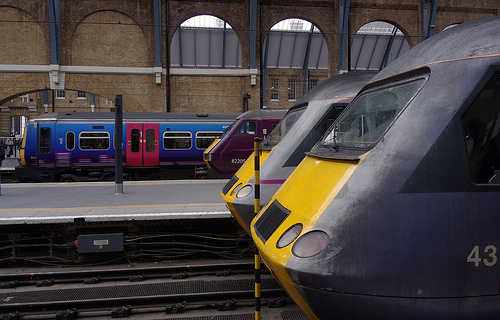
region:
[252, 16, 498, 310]
a grey and yellow train parked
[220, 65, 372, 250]
a grey and yellow train parked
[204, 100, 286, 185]
a grey and yellow train parked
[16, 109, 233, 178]
a blue red and yellow train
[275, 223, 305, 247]
a round train headlight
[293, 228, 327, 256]
a round train headlight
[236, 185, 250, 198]
a round train headlight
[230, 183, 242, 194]
a round train headlight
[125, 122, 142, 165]
red door of a train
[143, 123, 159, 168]
red door of a train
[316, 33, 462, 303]
yellow and gray train in station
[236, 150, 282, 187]
yellow and gray train in station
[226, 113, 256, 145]
purple and gray train in station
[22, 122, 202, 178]
red and blue train in station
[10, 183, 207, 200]
gray platform in train station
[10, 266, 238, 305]
gray and brown metal tracks in station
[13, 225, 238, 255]
gray and brown metal tracks in station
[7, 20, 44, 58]
brown and tan wall in train station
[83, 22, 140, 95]
brown gray and tan wall in train station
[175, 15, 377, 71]
windows in train station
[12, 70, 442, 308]
several trains in photograph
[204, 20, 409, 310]
two black and yellow trains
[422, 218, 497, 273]
white numbers on black train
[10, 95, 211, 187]
blue and red train in photograph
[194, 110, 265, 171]
purple and yellow train in photograph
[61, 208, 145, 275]
black box with wires on train tracks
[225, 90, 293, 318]
black and yellow striped pole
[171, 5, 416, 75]
three arched windows in photo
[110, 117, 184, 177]
red doors on blue train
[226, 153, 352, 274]
yellow noses of trains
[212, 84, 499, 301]
trains parked in station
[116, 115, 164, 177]
pink doors on train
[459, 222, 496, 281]
white numbers on train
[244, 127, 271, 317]
black and yellow pole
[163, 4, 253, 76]
arched window of station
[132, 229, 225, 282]
cables above train tracks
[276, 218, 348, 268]
lights on front of train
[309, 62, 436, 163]
windshield on front of train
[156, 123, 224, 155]
windows on side of train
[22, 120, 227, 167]
back train is mainly blue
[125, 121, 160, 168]
train door is red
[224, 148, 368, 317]
front of trains is yellow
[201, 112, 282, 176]
The train is purple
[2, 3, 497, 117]
Wall of station is made of bricks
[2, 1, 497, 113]
Train station wall is brown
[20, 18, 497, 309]
There are four trains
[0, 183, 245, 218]
Platform is gray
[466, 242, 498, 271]
Front train has white 43 on it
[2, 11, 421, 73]
There are five arches